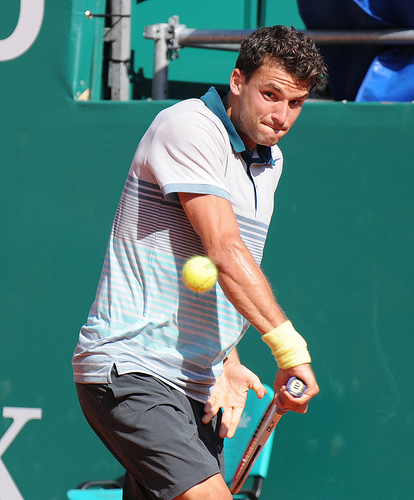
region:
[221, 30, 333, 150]
head of a person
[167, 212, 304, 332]
arm of a person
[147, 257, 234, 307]
ball in mid air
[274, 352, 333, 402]
hand of a person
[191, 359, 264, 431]
hand of a person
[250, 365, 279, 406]
thumb of a person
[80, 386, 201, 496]
thigh of a person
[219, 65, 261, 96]
ear of a person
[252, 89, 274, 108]
eye of a person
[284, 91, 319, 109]
eye of a person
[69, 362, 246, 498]
Man wearing shorts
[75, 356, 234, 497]
Man is wearing shorts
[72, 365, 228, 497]
Man wearing gray shorts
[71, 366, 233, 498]
Man is wearing gray shorts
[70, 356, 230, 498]
Man wearing dark gray shorts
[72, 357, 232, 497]
Man is wearing dark gray shorts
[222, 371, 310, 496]
Man is holding a racket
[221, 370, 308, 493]
Man is holding a tennis racket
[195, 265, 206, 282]
Part of the ball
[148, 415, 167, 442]
Part of the shorts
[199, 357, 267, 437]
The left hand of the person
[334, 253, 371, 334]
Part of the blue wall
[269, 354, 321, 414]
The right hand of the person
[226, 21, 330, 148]
The head of the person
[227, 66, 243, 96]
The right ear of the person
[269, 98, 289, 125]
The nose of the person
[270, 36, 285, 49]
Part of the hair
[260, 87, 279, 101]
The right eye of the person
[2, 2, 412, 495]
man is playing tennis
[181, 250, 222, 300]
ball is in the air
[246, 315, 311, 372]
man wearing a wristband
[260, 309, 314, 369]
the wristband is yellow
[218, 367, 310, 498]
man holding a racket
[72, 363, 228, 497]
man is wearing shorts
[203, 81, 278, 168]
collar on shirt is blue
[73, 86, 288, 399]
man's shirt is striped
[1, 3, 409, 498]
wall behind man is green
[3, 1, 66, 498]
white letters on wall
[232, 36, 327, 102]
man has brown hair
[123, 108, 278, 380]
blue and grey shirt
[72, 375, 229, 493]
man has grey shorts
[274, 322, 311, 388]
man has yellow wristband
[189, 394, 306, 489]
green chair behind man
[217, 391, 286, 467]
man has white racket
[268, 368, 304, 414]
black grip on white racket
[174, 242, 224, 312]
yellow ball in air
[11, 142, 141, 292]
green wall behind man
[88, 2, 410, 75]
grey rails on wall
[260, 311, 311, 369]
yellow wristband man is wearing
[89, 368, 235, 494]
gray shorts man is wearing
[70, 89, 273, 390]
blue and white striped shirt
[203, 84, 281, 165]
collar on the shirt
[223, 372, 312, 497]
racket the man is holding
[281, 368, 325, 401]
logo on the bottom of racket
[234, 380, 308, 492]
racket is orange in color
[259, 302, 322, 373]
man is wearing a wristband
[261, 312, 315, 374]
wristband is yellow in color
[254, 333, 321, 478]
man is holding a racket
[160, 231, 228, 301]
tennis ball is in the air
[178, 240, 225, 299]
tennis ball is yellow in color